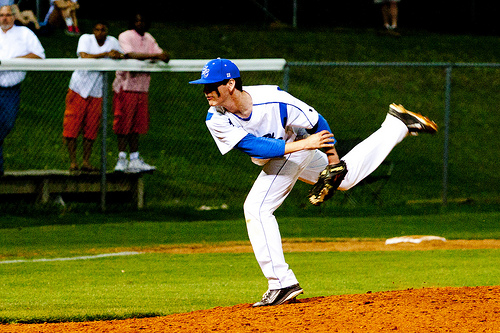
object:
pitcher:
[188, 57, 437, 308]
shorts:
[113, 91, 149, 135]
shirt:
[0, 26, 46, 88]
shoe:
[127, 159, 155, 172]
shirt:
[69, 34, 126, 99]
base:
[385, 236, 447, 245]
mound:
[0, 285, 500, 332]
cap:
[189, 58, 241, 85]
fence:
[0, 58, 500, 214]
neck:
[220, 88, 251, 113]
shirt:
[205, 85, 337, 159]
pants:
[243, 113, 408, 290]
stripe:
[264, 235, 283, 288]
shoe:
[388, 102, 437, 136]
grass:
[2, 251, 118, 316]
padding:
[0, 58, 286, 71]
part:
[160, 258, 240, 279]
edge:
[389, 102, 438, 131]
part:
[359, 143, 380, 161]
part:
[370, 62, 440, 66]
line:
[0, 251, 139, 264]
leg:
[243, 160, 311, 278]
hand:
[304, 130, 334, 150]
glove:
[306, 160, 348, 206]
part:
[333, 169, 344, 175]